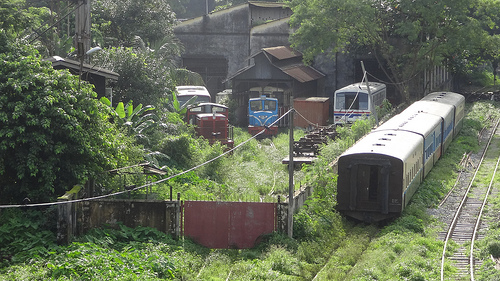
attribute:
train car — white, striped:
[326, 69, 398, 136]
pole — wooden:
[282, 99, 300, 245]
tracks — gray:
[447, 87, 497, 269]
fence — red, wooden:
[180, 200, 274, 248]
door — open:
[352, 167, 387, 214]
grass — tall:
[3, 209, 199, 276]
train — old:
[310, 46, 499, 243]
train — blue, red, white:
[241, 90, 284, 137]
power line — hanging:
[12, 81, 373, 222]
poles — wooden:
[257, 73, 314, 243]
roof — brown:
[268, 50, 315, 82]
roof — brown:
[258, 34, 310, 82]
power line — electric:
[0, 108, 293, 208]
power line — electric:
[292, 73, 362, 132]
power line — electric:
[366, 68, 417, 83]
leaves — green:
[83, 102, 148, 144]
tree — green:
[3, 28, 153, 233]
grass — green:
[0, 90, 480, 279]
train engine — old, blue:
[244, 85, 288, 137]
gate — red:
[180, 195, 277, 252]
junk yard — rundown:
[58, 36, 399, 258]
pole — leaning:
[357, 55, 380, 116]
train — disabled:
[329, 86, 467, 227]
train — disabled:
[285, 77, 388, 167]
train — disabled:
[245, 82, 285, 138]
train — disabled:
[173, 85, 235, 155]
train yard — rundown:
[0, 0, 499, 280]